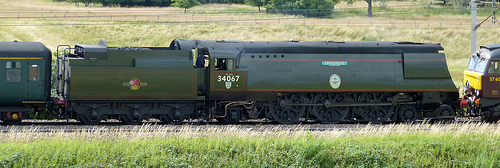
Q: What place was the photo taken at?
A: It was taken at the field.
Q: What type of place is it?
A: It is a field.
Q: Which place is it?
A: It is a field.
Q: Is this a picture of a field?
A: Yes, it is showing a field.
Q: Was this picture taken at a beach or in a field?
A: It was taken at a field.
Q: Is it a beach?
A: No, it is a field.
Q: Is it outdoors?
A: Yes, it is outdoors.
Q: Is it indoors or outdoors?
A: It is outdoors.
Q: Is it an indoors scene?
A: No, it is outdoors.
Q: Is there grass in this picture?
A: Yes, there is grass.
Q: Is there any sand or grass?
A: Yes, there is grass.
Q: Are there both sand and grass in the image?
A: No, there is grass but no sand.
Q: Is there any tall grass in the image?
A: Yes, there is tall grass.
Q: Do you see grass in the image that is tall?
A: Yes, there is grass that is tall.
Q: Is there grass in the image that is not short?
A: Yes, there is tall grass.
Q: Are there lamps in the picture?
A: No, there are no lamps.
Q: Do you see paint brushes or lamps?
A: No, there are no lamps or paint brushes.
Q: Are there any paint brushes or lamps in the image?
A: No, there are no lamps or paint brushes.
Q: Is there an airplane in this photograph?
A: No, there are no airplanes.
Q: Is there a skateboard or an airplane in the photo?
A: No, there are no airplanes or skateboards.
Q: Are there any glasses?
A: No, there are no glasses.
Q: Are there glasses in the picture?
A: No, there are no glasses.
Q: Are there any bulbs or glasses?
A: No, there are no glasses or bulbs.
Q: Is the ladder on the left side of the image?
A: Yes, the ladder is on the left of the image.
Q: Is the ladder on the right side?
A: No, the ladder is on the left of the image.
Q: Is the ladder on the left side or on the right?
A: The ladder is on the left of the image.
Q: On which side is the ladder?
A: The ladder is on the left of the image.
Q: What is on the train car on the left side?
A: The ladder is on the train car.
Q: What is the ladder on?
A: The ladder is on the train car.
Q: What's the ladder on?
A: The ladder is on the train car.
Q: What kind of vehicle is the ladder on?
A: The ladder is on the train car.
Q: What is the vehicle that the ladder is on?
A: The vehicle is a train car.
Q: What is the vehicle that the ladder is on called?
A: The vehicle is a train car.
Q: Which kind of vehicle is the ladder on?
A: The ladder is on the train car.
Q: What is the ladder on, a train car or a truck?
A: The ladder is on a train car.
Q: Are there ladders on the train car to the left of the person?
A: Yes, there is a ladder on the train car.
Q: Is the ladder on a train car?
A: Yes, the ladder is on a train car.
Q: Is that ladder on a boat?
A: No, the ladder is on a train car.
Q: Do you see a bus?
A: No, there are no buses.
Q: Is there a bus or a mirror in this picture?
A: No, there are no buses or mirrors.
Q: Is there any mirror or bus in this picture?
A: No, there are no buses or mirrors.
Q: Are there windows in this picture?
A: Yes, there is a window.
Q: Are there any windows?
A: Yes, there is a window.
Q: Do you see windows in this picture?
A: Yes, there is a window.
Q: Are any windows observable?
A: Yes, there is a window.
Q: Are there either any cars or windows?
A: Yes, there is a window.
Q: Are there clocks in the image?
A: No, there are no clocks.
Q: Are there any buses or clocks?
A: No, there are no clocks or buses.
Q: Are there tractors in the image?
A: No, there are no tractors.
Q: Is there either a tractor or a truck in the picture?
A: No, there are no tractors or trucks.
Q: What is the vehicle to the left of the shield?
A: The vehicle is a train car.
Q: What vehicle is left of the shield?
A: The vehicle is a train car.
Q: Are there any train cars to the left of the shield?
A: Yes, there is a train car to the left of the shield.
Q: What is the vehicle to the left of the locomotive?
A: The vehicle is a train car.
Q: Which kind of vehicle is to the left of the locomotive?
A: The vehicle is a train car.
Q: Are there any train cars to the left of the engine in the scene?
A: Yes, there is a train car to the left of the engine.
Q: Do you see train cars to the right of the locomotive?
A: No, the train car is to the left of the locomotive.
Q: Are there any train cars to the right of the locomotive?
A: No, the train car is to the left of the locomotive.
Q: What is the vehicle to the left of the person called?
A: The vehicle is a train car.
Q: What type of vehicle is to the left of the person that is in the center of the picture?
A: The vehicle is a train car.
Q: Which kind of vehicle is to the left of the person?
A: The vehicle is a train car.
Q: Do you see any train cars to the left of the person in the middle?
A: Yes, there is a train car to the left of the person.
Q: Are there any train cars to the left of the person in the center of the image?
A: Yes, there is a train car to the left of the person.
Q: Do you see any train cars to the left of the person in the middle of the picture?
A: Yes, there is a train car to the left of the person.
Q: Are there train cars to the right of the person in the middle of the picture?
A: No, the train car is to the left of the person.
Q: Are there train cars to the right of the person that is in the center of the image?
A: No, the train car is to the left of the person.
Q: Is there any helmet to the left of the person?
A: No, there is a train car to the left of the person.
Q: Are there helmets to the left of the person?
A: No, there is a train car to the left of the person.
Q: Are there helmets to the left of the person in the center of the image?
A: No, there is a train car to the left of the person.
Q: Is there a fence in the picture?
A: Yes, there is a fence.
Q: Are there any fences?
A: Yes, there is a fence.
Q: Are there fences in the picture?
A: Yes, there is a fence.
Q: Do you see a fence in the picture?
A: Yes, there is a fence.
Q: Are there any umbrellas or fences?
A: Yes, there is a fence.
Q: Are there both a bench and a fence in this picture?
A: No, there is a fence but no benches.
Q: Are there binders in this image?
A: No, there are no binders.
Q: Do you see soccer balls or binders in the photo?
A: No, there are no binders or soccer balls.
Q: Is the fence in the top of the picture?
A: Yes, the fence is in the top of the image.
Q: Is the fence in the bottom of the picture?
A: No, the fence is in the top of the image.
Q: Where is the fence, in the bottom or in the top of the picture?
A: The fence is in the top of the image.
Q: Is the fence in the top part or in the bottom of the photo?
A: The fence is in the top of the image.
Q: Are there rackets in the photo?
A: No, there are no rackets.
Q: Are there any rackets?
A: No, there are no rackets.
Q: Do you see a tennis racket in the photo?
A: No, there are no rackets.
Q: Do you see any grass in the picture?
A: Yes, there is grass.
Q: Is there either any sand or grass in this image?
A: Yes, there is grass.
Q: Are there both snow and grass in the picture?
A: No, there is grass but no snow.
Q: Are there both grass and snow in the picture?
A: No, there is grass but no snow.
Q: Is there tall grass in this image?
A: Yes, there is tall grass.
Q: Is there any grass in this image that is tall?
A: Yes, there is tall grass.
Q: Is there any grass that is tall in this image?
A: Yes, there is tall grass.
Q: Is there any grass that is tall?
A: Yes, there is grass that is tall.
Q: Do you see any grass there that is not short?
A: Yes, there is tall grass.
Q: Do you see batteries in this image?
A: No, there are no batteries.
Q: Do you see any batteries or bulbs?
A: No, there are no batteries or bulbs.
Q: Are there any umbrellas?
A: No, there are no umbrellas.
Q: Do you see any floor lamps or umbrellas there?
A: No, there are no umbrellas or floor lamps.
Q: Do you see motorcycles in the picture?
A: No, there are no motorcycles.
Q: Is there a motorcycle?
A: No, there are no motorcycles.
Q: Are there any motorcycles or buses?
A: No, there are no motorcycles or buses.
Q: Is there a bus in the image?
A: No, there are no buses.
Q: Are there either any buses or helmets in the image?
A: No, there are no buses or helmets.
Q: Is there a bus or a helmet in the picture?
A: No, there are no buses or helmets.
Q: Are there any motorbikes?
A: No, there are no motorbikes.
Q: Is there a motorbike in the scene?
A: No, there are no motorcycles.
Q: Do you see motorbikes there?
A: No, there are no motorbikes.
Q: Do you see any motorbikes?
A: No, there are no motorbikes.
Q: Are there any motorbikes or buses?
A: No, there are no motorbikes or buses.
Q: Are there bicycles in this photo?
A: No, there are no bicycles.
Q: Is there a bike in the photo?
A: No, there are no bikes.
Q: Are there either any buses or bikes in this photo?
A: No, there are no bikes or buses.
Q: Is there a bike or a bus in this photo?
A: No, there are no bikes or buses.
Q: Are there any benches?
A: No, there are no benches.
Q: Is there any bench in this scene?
A: No, there are no benches.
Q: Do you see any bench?
A: No, there are no benches.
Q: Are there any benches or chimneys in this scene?
A: No, there are no benches or chimneys.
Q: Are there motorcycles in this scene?
A: No, there are no motorcycles.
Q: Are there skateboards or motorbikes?
A: No, there are no motorbikes or skateboards.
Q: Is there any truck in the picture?
A: No, there are no trucks.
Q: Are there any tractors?
A: No, there are no tractors.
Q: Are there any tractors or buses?
A: No, there are no tractors or buses.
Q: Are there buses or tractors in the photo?
A: No, there are no tractors or buses.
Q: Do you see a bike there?
A: No, there are no bikes.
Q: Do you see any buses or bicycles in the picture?
A: No, there are no bicycles or buses.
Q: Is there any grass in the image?
A: Yes, there is grass.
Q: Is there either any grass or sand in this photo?
A: Yes, there is grass.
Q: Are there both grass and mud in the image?
A: No, there is grass but no mud.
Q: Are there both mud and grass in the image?
A: No, there is grass but no mud.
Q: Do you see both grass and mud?
A: No, there is grass but no mud.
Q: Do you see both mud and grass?
A: No, there is grass but no mud.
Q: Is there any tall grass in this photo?
A: Yes, there is tall grass.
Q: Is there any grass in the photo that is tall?
A: Yes, there is grass that is tall.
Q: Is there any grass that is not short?
A: Yes, there is tall grass.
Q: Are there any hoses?
A: No, there are no hoses.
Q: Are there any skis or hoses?
A: No, there are no hoses or skis.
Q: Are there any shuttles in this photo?
A: No, there are no shuttles.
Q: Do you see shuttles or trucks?
A: No, there are no shuttles or trucks.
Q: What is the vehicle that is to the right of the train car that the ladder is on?
A: The vehicle is a locomotive.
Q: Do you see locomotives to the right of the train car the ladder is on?
A: Yes, there is a locomotive to the right of the train car.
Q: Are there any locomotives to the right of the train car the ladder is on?
A: Yes, there is a locomotive to the right of the train car.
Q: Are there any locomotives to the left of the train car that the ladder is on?
A: No, the locomotive is to the right of the train car.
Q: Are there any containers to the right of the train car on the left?
A: No, there is a locomotive to the right of the train car.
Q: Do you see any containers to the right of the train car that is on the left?
A: No, there is a locomotive to the right of the train car.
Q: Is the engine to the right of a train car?
A: Yes, the engine is to the right of a train car.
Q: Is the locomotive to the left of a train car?
A: No, the locomotive is to the right of a train car.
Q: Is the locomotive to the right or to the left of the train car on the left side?
A: The locomotive is to the right of the train car.